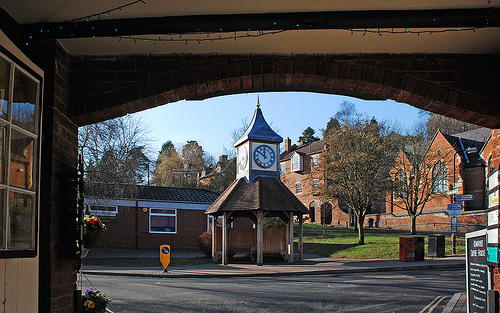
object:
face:
[255, 145, 276, 169]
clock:
[253, 144, 276, 169]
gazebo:
[202, 94, 306, 266]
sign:
[159, 244, 171, 273]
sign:
[463, 228, 492, 313]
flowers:
[81, 214, 107, 250]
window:
[4, 190, 37, 250]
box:
[399, 236, 416, 262]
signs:
[446, 183, 477, 255]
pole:
[451, 232, 456, 254]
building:
[82, 179, 220, 259]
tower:
[234, 95, 286, 183]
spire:
[255, 93, 261, 109]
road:
[89, 261, 471, 310]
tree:
[383, 149, 458, 235]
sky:
[155, 109, 230, 143]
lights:
[21, 40, 30, 47]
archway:
[224, 210, 258, 265]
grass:
[311, 244, 398, 258]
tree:
[305, 118, 395, 243]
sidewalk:
[112, 246, 415, 271]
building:
[285, 132, 496, 234]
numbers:
[263, 146, 267, 150]